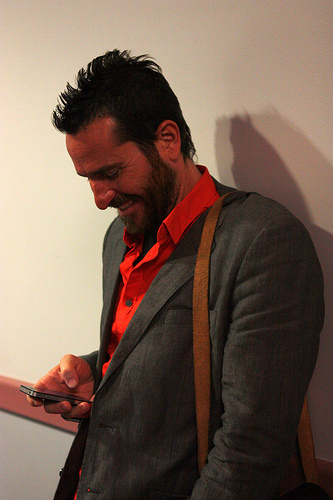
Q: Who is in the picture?
A: A man.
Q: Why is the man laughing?
A: He got a text.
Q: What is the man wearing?
A: A suit.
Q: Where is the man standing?
A: Against a wall.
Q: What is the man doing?
A: Texting.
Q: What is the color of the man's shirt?
A: Red.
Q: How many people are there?
A: One.